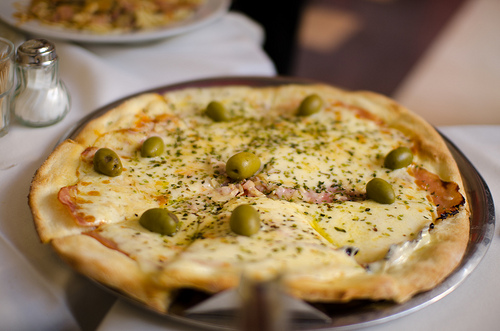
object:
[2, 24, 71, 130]
salt shaker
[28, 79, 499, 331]
pizza pan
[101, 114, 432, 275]
pizza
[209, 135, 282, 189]
green olives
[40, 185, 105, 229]
ham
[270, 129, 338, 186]
cheese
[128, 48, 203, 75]
tablecloth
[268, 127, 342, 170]
green herbs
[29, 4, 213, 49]
food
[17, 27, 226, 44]
plate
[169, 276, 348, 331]
spatula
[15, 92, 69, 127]
salt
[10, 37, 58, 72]
top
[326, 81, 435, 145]
pizza crust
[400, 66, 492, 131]
small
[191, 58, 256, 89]
edge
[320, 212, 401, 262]
melted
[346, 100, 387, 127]
sauce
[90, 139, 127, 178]
green olive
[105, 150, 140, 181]
hole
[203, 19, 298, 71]
table